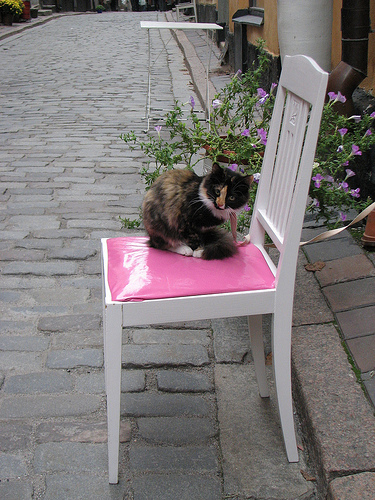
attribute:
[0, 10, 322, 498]
sidewalk — gray, brick, walkpath, cobblestones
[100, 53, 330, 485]
chair — standing, white, wooden, pink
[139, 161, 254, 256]
cat — calico, a tabby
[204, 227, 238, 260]
tail — fluffy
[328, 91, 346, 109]
flower — purple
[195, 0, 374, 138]
wall — yellow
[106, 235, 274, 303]
seat — shiny, pink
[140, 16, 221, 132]
tray table — white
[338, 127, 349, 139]
flower — purple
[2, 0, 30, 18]
flowers — yellow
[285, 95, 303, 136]
design — carved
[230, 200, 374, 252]
leash — white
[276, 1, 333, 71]
pillar — fat, white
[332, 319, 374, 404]
grass — growing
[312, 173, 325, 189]
flower — purple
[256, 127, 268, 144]
flower — purple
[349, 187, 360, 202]
flower — purple